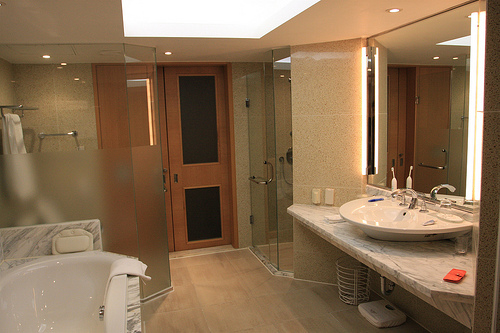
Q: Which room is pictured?
A: It is a bathroom.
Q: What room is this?
A: It is a bathroom.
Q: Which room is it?
A: It is a bathroom.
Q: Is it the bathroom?
A: Yes, it is the bathroom.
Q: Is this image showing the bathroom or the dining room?
A: It is showing the bathroom.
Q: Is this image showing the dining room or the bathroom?
A: It is showing the bathroom.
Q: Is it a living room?
A: No, it is a bathroom.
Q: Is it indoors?
A: Yes, it is indoors.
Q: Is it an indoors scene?
A: Yes, it is indoors.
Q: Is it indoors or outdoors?
A: It is indoors.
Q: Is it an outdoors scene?
A: No, it is indoors.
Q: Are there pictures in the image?
A: No, there are no pictures.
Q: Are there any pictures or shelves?
A: No, there are no pictures or shelves.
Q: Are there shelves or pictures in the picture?
A: No, there are no pictures or shelves.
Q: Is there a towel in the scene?
A: Yes, there is a towel.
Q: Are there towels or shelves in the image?
A: Yes, there is a towel.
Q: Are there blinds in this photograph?
A: No, there are no blinds.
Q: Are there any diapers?
A: No, there are no diapers.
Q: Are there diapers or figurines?
A: No, there are no diapers or figurines.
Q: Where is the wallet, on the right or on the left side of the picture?
A: The wallet is on the right of the image.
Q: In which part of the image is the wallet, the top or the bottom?
A: The wallet is in the bottom of the image.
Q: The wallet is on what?
A: The wallet is on the counter.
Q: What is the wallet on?
A: The wallet is on the counter.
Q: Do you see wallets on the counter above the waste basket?
A: Yes, there is a wallet on the counter.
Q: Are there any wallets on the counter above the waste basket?
A: Yes, there is a wallet on the counter.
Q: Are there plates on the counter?
A: No, there is a wallet on the counter.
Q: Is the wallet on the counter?
A: Yes, the wallet is on the counter.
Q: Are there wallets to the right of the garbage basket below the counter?
A: Yes, there is a wallet to the right of the waste basket.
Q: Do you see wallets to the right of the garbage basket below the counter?
A: Yes, there is a wallet to the right of the waste basket.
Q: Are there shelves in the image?
A: No, there are no shelves.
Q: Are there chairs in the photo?
A: No, there are no chairs.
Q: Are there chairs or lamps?
A: No, there are no chairs or lamps.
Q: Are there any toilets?
A: No, there are no toilets.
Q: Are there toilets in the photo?
A: No, there are no toilets.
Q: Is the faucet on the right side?
A: Yes, the faucet is on the right of the image.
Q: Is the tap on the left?
A: No, the tap is on the right of the image.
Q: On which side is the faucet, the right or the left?
A: The faucet is on the right of the image.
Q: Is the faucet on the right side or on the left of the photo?
A: The faucet is on the right of the image.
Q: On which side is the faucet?
A: The faucet is on the right of the image.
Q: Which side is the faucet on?
A: The faucet is on the right of the image.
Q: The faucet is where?
A: The faucet is in the bathroom.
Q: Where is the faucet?
A: The faucet is in the bathroom.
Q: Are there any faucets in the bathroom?
A: Yes, there is a faucet in the bathroom.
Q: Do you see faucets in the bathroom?
A: Yes, there is a faucet in the bathroom.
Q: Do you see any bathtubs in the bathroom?
A: No, there is a faucet in the bathroom.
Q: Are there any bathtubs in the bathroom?
A: No, there is a faucet in the bathroom.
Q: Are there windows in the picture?
A: Yes, there is a window.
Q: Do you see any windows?
A: Yes, there is a window.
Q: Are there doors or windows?
A: Yes, there is a window.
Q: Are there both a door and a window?
A: Yes, there are both a window and a door.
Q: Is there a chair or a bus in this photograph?
A: No, there are no chairs or buses.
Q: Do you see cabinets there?
A: No, there are no cabinets.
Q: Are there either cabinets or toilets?
A: No, there are no cabinets or toilets.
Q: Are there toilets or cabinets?
A: No, there are no cabinets or toilets.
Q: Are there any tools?
A: No, there are no tools.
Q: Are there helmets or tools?
A: No, there are no tools or helmets.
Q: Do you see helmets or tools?
A: No, there are no tools or helmets.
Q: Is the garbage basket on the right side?
A: Yes, the garbage basket is on the right of the image.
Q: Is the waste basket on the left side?
A: No, the waste basket is on the right of the image.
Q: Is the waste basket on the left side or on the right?
A: The waste basket is on the right of the image.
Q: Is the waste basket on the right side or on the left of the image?
A: The waste basket is on the right of the image.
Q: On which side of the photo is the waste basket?
A: The waste basket is on the right of the image.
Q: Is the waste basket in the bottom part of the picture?
A: Yes, the waste basket is in the bottom of the image.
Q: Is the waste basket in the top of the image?
A: No, the waste basket is in the bottom of the image.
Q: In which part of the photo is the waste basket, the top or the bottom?
A: The waste basket is in the bottom of the image.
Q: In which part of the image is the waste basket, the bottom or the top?
A: The waste basket is in the bottom of the image.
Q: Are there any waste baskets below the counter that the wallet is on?
A: Yes, there is a waste basket below the counter.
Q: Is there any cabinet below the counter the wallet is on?
A: No, there is a waste basket below the counter.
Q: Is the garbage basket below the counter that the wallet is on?
A: Yes, the garbage basket is below the counter.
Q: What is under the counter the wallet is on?
A: The garbage basket is under the counter.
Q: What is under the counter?
A: The garbage basket is under the counter.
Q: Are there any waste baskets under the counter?
A: Yes, there is a waste basket under the counter.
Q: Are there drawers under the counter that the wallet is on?
A: No, there is a waste basket under the counter.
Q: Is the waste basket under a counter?
A: Yes, the waste basket is under a counter.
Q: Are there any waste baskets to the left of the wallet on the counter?
A: Yes, there is a waste basket to the left of the wallet.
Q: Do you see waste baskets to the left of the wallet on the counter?
A: Yes, there is a waste basket to the left of the wallet.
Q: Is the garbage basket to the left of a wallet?
A: Yes, the garbage basket is to the left of a wallet.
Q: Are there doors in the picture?
A: Yes, there is a door.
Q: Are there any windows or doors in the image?
A: Yes, there is a door.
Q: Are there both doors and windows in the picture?
A: Yes, there are both a door and a window.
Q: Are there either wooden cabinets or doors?
A: Yes, there is a wood door.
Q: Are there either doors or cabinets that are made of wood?
A: Yes, the door is made of wood.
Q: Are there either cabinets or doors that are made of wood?
A: Yes, the door is made of wood.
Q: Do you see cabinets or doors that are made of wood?
A: Yes, the door is made of wood.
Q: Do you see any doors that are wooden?
A: Yes, there is a wood door.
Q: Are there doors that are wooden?
A: Yes, there is a door that is wooden.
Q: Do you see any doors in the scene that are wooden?
A: Yes, there is a door that is wooden.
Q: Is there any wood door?
A: Yes, there is a door that is made of wood.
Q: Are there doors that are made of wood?
A: Yes, there is a door that is made of wood.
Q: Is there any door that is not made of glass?
A: Yes, there is a door that is made of wood.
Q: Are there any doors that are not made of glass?
A: Yes, there is a door that is made of wood.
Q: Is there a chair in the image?
A: No, there are no chairs.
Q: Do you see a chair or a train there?
A: No, there are no chairs or trains.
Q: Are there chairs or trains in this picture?
A: No, there are no chairs or trains.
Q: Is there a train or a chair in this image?
A: No, there are no chairs or trains.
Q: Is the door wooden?
A: Yes, the door is wooden.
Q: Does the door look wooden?
A: Yes, the door is wooden.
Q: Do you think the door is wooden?
A: Yes, the door is wooden.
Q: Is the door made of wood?
A: Yes, the door is made of wood.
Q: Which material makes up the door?
A: The door is made of wood.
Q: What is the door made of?
A: The door is made of wood.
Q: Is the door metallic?
A: No, the door is wooden.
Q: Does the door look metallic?
A: No, the door is wooden.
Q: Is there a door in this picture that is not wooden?
A: No, there is a door but it is wooden.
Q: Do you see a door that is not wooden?
A: No, there is a door but it is wooden.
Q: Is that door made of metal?
A: No, the door is made of wood.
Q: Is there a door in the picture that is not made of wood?
A: No, there is a door but it is made of wood.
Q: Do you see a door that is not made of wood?
A: No, there is a door but it is made of wood.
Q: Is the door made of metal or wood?
A: The door is made of wood.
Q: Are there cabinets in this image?
A: No, there are no cabinets.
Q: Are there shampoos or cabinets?
A: No, there are no cabinets or shampoos.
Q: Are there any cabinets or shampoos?
A: No, there are no cabinets or shampoos.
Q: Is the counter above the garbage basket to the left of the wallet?
A: Yes, the counter is above the waste basket.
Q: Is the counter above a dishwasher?
A: No, the counter is above the waste basket.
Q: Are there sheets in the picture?
A: No, there are no sheets.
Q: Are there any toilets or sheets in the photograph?
A: No, there are no sheets or toilets.